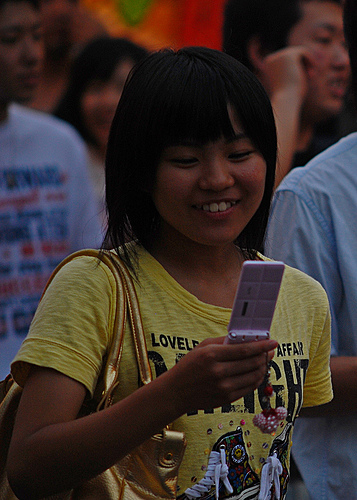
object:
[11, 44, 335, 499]
girl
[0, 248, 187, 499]
handbag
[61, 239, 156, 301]
shoulder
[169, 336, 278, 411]
hand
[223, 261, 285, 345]
phone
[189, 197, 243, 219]
mouth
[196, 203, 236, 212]
teeth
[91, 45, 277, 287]
hair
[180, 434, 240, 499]
lace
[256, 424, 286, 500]
lace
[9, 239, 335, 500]
shirt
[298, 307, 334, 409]
sleeve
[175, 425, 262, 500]
shoe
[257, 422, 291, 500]
shoe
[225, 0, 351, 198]
man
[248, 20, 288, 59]
phone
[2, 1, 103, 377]
man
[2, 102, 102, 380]
shirt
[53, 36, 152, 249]
woman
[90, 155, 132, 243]
shirt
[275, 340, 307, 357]
words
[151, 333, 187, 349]
love